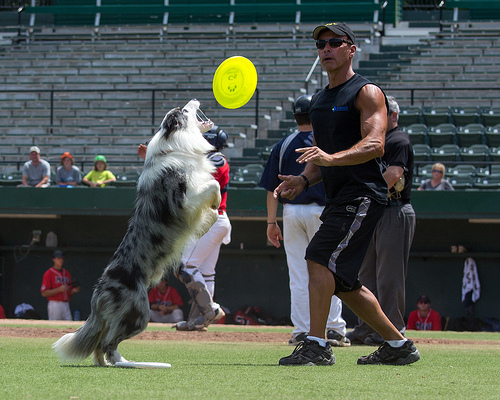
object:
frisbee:
[211, 56, 258, 109]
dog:
[53, 97, 222, 366]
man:
[273, 19, 420, 366]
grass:
[0, 317, 499, 399]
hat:
[313, 22, 355, 48]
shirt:
[304, 72, 389, 204]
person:
[417, 161, 452, 192]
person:
[83, 155, 115, 186]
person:
[54, 151, 81, 186]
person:
[17, 146, 50, 188]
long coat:
[52, 96, 217, 363]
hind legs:
[91, 281, 125, 363]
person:
[261, 94, 349, 347]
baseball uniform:
[257, 129, 347, 335]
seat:
[430, 123, 454, 142]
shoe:
[277, 338, 334, 367]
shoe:
[358, 338, 418, 366]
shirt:
[84, 170, 113, 186]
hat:
[61, 151, 72, 159]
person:
[405, 295, 440, 331]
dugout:
[0, 185, 499, 331]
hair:
[386, 94, 400, 120]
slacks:
[346, 196, 414, 340]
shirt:
[381, 128, 415, 206]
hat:
[94, 154, 108, 164]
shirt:
[55, 160, 83, 183]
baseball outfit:
[42, 264, 77, 320]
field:
[0, 317, 499, 400]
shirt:
[147, 284, 182, 310]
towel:
[460, 256, 482, 306]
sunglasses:
[316, 38, 351, 49]